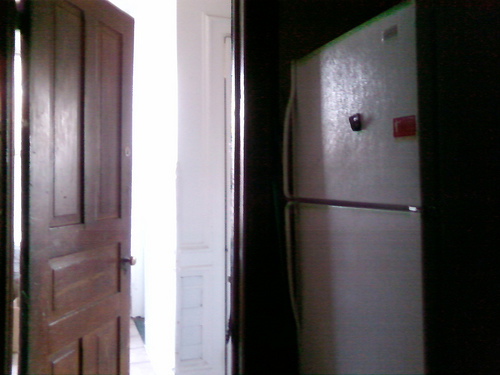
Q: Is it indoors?
A: Yes, it is indoors.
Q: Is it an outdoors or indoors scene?
A: It is indoors.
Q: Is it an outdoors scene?
A: No, it is indoors.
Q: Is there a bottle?
A: No, there are no bottles.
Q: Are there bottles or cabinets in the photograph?
A: No, there are no bottles or cabinets.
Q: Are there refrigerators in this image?
A: Yes, there is a refrigerator.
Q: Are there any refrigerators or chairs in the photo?
A: Yes, there is a refrigerator.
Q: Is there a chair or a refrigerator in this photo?
A: Yes, there is a refrigerator.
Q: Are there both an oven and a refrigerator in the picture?
A: No, there is a refrigerator but no ovens.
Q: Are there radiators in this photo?
A: No, there are no radiators.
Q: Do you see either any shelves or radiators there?
A: No, there are no radiators or shelves.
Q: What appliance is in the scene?
A: The appliance is a refrigerator.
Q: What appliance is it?
A: The appliance is a refrigerator.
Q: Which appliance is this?
A: This is a refrigerator.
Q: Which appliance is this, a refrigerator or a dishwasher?
A: This is a refrigerator.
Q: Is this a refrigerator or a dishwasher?
A: This is a refrigerator.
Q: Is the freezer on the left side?
A: No, the freezer is on the right of the image.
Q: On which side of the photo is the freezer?
A: The freezer is on the right of the image.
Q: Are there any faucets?
A: No, there are no faucets.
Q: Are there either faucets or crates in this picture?
A: No, there are no faucets or crates.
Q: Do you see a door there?
A: Yes, there is a door.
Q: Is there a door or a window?
A: Yes, there is a door.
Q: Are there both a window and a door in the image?
A: No, there is a door but no windows.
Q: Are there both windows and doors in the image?
A: No, there is a door but no windows.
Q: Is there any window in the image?
A: No, there are no windows.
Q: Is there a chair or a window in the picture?
A: No, there are no windows or chairs.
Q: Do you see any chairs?
A: No, there are no chairs.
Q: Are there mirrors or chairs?
A: No, there are no chairs or mirrors.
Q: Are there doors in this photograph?
A: Yes, there is a door.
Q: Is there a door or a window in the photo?
A: Yes, there is a door.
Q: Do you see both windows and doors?
A: No, there is a door but no windows.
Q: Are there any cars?
A: No, there are no cars.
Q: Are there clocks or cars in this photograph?
A: No, there are no cars or clocks.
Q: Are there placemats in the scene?
A: No, there are no placemats.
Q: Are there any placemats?
A: No, there are no placemats.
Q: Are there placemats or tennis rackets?
A: No, there are no placemats or tennis rackets.